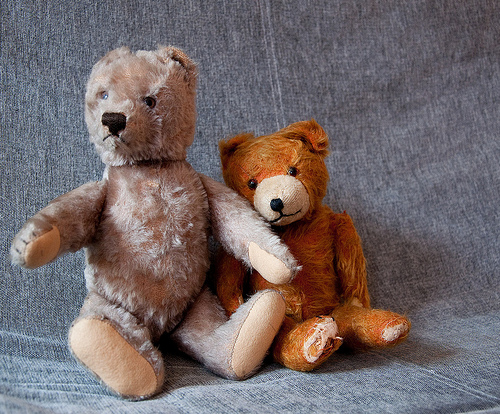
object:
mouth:
[102, 132, 130, 148]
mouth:
[266, 206, 305, 224]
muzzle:
[249, 174, 310, 226]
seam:
[256, 1, 496, 412]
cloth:
[2, 0, 497, 412]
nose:
[270, 198, 284, 212]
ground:
[0, 0, 499, 413]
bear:
[8, 44, 301, 402]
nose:
[101, 111, 127, 134]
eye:
[96, 87, 108, 102]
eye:
[142, 95, 157, 110]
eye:
[247, 177, 259, 190]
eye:
[287, 166, 298, 177]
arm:
[6, 180, 106, 269]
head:
[83, 44, 196, 167]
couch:
[0, 0, 498, 410]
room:
[0, 0, 497, 410]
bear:
[213, 120, 413, 373]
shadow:
[316, 178, 458, 373]